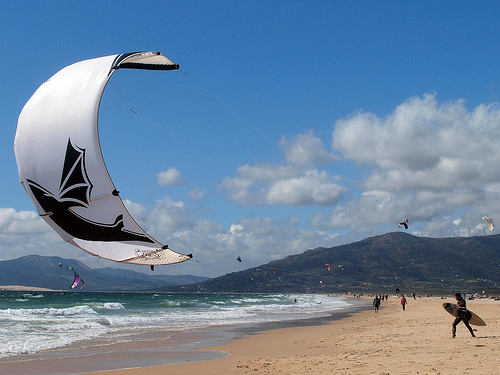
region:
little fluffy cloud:
[248, 165, 351, 214]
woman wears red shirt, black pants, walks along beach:
[397, 290, 411, 312]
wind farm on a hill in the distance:
[413, 222, 490, 241]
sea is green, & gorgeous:
[0, 288, 296, 318]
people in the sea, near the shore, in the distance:
[286, 294, 332, 308]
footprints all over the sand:
[223, 312, 499, 373]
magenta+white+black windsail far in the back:
[65, 262, 84, 292]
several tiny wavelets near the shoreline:
[0, 299, 127, 359]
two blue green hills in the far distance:
[0, 250, 227, 291]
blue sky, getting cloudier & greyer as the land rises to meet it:
[0, 0, 499, 280]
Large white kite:
[12, 48, 191, 268]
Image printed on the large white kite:
[22, 135, 157, 246]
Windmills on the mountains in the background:
[411, 221, 492, 238]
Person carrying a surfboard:
[442, 289, 489, 340]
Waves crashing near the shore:
[0, 293, 350, 355]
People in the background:
[352, 289, 497, 314]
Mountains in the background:
[1, 229, 499, 293]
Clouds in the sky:
[2, 86, 499, 260]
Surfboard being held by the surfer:
[439, 300, 488, 328]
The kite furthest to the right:
[480, 213, 496, 235]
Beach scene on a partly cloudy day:
[9, 5, 494, 372]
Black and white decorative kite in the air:
[11, 29, 209, 289]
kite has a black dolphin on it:
[16, 50, 192, 294]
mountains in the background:
[205, 118, 497, 333]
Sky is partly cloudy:
[0, 8, 488, 373]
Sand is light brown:
[81, 190, 490, 368]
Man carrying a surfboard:
[414, 267, 490, 350]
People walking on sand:
[345, 260, 422, 350]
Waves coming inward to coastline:
[35, 281, 370, 358]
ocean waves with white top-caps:
[0, 272, 345, 366]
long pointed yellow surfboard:
[441, 299, 486, 327]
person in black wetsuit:
[449, 288, 472, 336]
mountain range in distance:
[187, 230, 499, 290]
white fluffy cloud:
[266, 172, 340, 206]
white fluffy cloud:
[337, 96, 499, 173]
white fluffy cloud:
[157, 163, 185, 185]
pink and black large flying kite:
[56, 260, 87, 288]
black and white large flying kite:
[12, 50, 202, 265]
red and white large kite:
[321, 260, 331, 270]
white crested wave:
[3, 301, 101, 321]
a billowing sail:
[11, 40, 195, 290]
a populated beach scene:
[8, 270, 498, 374]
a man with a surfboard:
[437, 289, 484, 346]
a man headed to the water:
[261, 288, 491, 347]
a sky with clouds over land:
[4, 14, 497, 275]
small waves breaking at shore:
[0, 277, 355, 353]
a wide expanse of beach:
[198, 298, 495, 373]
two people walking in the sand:
[359, 294, 410, 314]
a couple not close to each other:
[360, 293, 417, 317]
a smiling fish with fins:
[24, 139, 153, 258]